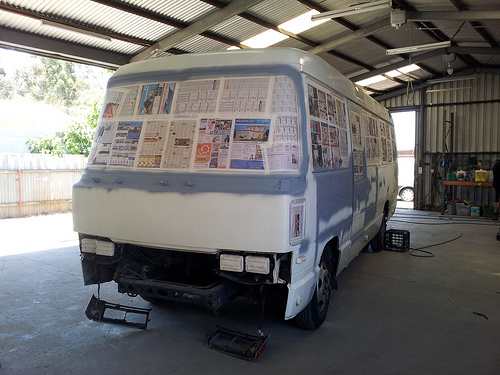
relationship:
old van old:
[67, 44, 400, 331] [67, 44, 400, 331]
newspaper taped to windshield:
[88, 70, 403, 173] [88, 71, 305, 182]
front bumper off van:
[73, 230, 301, 323] [74, 230, 316, 323]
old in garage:
[67, 44, 400, 331] [0, 0, 500, 375]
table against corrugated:
[435, 175, 499, 215] [419, 71, 500, 213]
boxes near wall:
[438, 195, 498, 219] [441, 194, 498, 217]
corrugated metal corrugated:
[419, 69, 499, 159] [419, 71, 500, 213]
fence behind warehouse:
[0, 149, 69, 221] [3, 150, 70, 218]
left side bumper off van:
[202, 321, 271, 363] [74, 230, 315, 364]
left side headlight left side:
[202, 321, 271, 363] [202, 321, 271, 363]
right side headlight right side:
[81, 293, 155, 335] [81, 293, 155, 335]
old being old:
[67, 44, 400, 331] [67, 44, 400, 331]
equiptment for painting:
[436, 120, 498, 191] [440, 118, 497, 186]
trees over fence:
[0, 99, 89, 163] [0, 152, 87, 221]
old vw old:
[67, 44, 400, 331] [67, 44, 400, 331]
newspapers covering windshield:
[85, 74, 306, 184] [88, 71, 305, 182]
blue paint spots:
[72, 163, 310, 200] [294, 219, 359, 258]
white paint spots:
[312, 201, 357, 230] [315, 199, 368, 233]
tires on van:
[290, 219, 388, 332] [292, 217, 388, 333]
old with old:
[67, 44, 400, 331] [67, 44, 400, 331]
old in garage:
[67, 44, 400, 331] [65, 16, 401, 359]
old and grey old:
[67, 44, 400, 331] [67, 44, 400, 331]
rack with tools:
[441, 154, 498, 191] [442, 154, 497, 190]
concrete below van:
[8, 252, 469, 367] [0, 256, 450, 374]